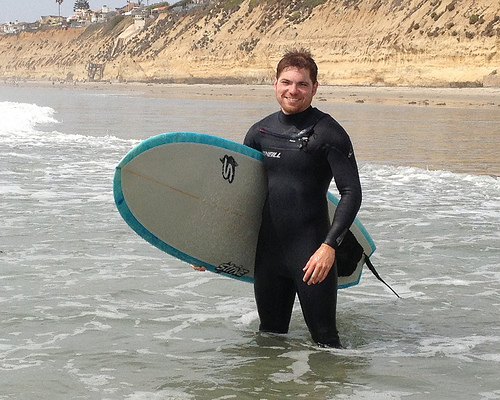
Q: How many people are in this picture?
A: 1.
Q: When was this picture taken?
A: Daytime.